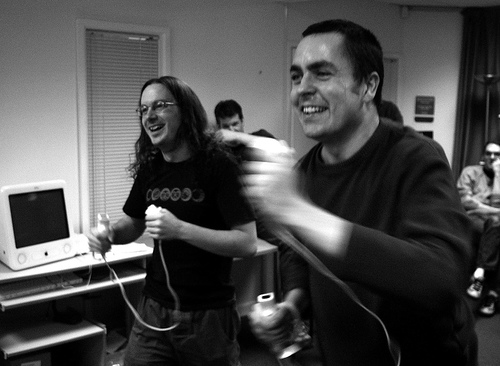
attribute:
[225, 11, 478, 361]
man — playing wii, here, smiling, playing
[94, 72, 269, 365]
man — playing wii, smiling, playing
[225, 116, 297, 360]
wii controllers — white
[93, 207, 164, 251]
wii controllers — white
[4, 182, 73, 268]
computer — off, apple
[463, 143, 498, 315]
man — sitting down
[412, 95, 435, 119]
sign — black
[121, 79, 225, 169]
hair — long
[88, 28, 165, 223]
blinds — white